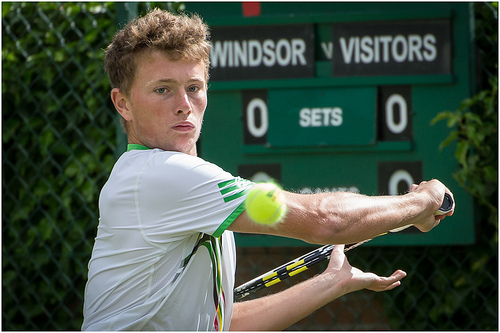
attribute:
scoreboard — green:
[231, 4, 484, 179]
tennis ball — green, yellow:
[245, 183, 291, 223]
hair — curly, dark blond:
[132, 22, 184, 45]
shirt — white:
[113, 132, 218, 332]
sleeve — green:
[162, 158, 254, 227]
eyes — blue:
[152, 82, 208, 100]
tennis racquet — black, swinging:
[242, 249, 319, 284]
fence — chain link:
[43, 48, 95, 129]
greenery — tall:
[450, 96, 499, 160]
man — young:
[105, 28, 227, 333]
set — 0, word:
[288, 98, 352, 144]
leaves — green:
[424, 102, 476, 146]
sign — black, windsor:
[235, 21, 449, 85]